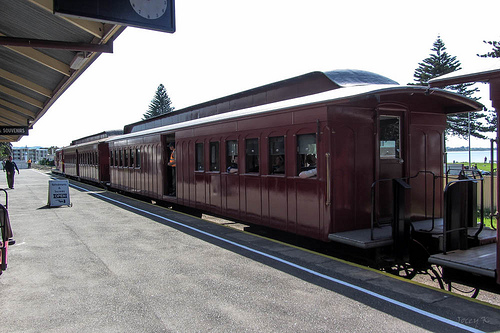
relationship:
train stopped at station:
[51, 58, 498, 301] [3, 2, 499, 330]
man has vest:
[168, 142, 177, 193] [167, 151, 176, 167]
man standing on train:
[168, 142, 177, 193] [51, 58, 498, 301]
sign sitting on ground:
[48, 177, 71, 209] [0, 168, 435, 332]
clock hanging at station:
[53, 3, 175, 31] [3, 2, 499, 330]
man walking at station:
[5, 158, 20, 188] [3, 2, 499, 330]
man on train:
[168, 142, 177, 193] [51, 58, 498, 301]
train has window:
[51, 58, 498, 301] [296, 131, 318, 178]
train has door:
[51, 58, 498, 301] [377, 112, 403, 221]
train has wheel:
[51, 58, 498, 301] [386, 253, 415, 279]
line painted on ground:
[51, 172, 500, 312] [0, 168, 435, 332]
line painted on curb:
[51, 172, 500, 312] [52, 173, 498, 318]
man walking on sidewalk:
[5, 158, 20, 188] [1, 169, 500, 332]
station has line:
[3, 2, 499, 330] [51, 172, 500, 312]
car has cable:
[107, 69, 485, 263] [397, 236, 482, 299]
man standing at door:
[168, 142, 177, 193] [159, 134, 179, 195]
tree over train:
[406, 34, 490, 144] [51, 58, 498, 301]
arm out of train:
[297, 167, 319, 179] [51, 58, 498, 301]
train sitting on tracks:
[51, 58, 498, 301] [396, 265, 498, 307]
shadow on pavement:
[47, 169, 500, 330] [1, 167, 500, 329]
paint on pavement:
[44, 173, 500, 332] [1, 167, 500, 329]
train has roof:
[51, 58, 498, 301] [54, 67, 499, 149]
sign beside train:
[48, 177, 71, 209] [51, 58, 498, 301]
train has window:
[51, 58, 498, 301] [266, 134, 288, 174]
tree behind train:
[406, 34, 490, 144] [51, 58, 498, 301]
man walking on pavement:
[5, 158, 20, 188] [1, 167, 500, 329]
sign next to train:
[48, 177, 71, 209] [51, 58, 498, 301]